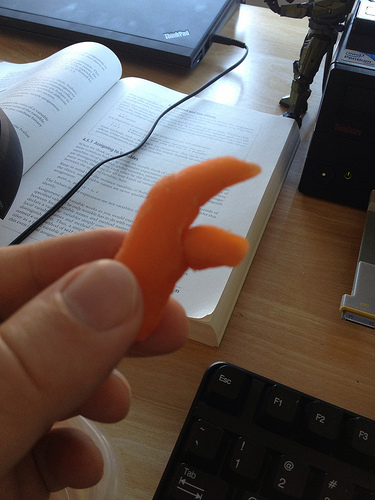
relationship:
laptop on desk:
[1, 0, 235, 75] [2, 6, 374, 499]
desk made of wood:
[2, 6, 374, 499] [0, 5, 374, 500]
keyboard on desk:
[148, 360, 369, 499] [2, 6, 374, 499]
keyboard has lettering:
[148, 360, 369, 499] [176, 373, 373, 499]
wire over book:
[5, 32, 249, 249] [2, 40, 299, 349]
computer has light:
[294, 0, 374, 211] [318, 171, 330, 179]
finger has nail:
[0, 258, 142, 477] [56, 258, 141, 336]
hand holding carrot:
[3, 227, 190, 500] [113, 155, 262, 344]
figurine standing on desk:
[262, 0, 352, 124] [2, 6, 374, 499]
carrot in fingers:
[105, 155, 261, 344] [3, 227, 190, 500]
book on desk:
[2, 40, 299, 349] [2, 6, 374, 499]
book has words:
[2, 40, 299, 349] [2, 46, 257, 298]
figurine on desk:
[262, 0, 352, 124] [2, 6, 374, 499]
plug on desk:
[336, 204, 374, 332] [2, 6, 374, 499]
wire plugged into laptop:
[5, 32, 249, 249] [1, 0, 235, 75]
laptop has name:
[1, 0, 235, 75] [161, 26, 190, 43]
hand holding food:
[3, 227, 190, 500] [105, 155, 261, 344]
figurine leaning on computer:
[262, 0, 352, 124] [294, 0, 374, 211]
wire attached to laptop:
[5, 32, 249, 249] [1, 0, 235, 75]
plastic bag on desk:
[43, 415, 121, 498] [2, 6, 374, 499]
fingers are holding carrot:
[3, 227, 190, 500] [105, 155, 261, 344]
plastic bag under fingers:
[43, 415, 121, 498] [3, 227, 190, 500]